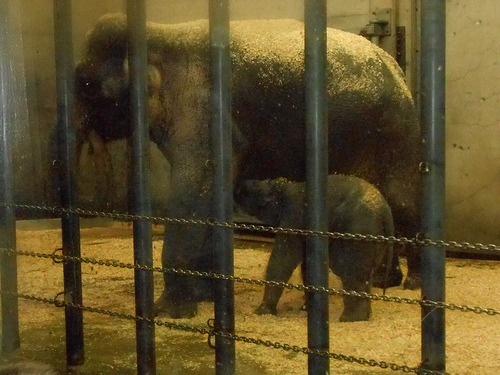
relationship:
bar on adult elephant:
[50, 0, 83, 370] [46, 12, 434, 318]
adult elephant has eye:
[46, 12, 434, 318] [66, 70, 103, 110]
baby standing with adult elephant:
[231, 172, 396, 323] [73, 12, 433, 307]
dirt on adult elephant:
[146, 16, 411, 97] [46, 12, 434, 318]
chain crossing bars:
[0, 199, 499, 259] [49, 4, 449, 371]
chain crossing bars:
[0, 246, 497, 313] [49, 4, 449, 371]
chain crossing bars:
[3, 285, 447, 373] [49, 4, 449, 371]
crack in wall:
[448, 34, 488, 81] [10, 3, 496, 257]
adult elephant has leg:
[46, 12, 434, 318] [141, 141, 223, 289]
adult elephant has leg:
[46, 12, 434, 318] [146, 201, 231, 306]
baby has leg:
[231, 172, 396, 323] [252, 228, 307, 318]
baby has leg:
[231, 172, 396, 323] [332, 271, 387, 326]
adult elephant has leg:
[46, 12, 434, 318] [383, 161, 445, 287]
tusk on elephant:
[80, 124, 115, 180] [40, 18, 491, 273]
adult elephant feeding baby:
[46, 12, 434, 318] [231, 172, 396, 323]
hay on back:
[363, 184, 381, 209] [328, 168, 397, 223]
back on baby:
[328, 168, 397, 223] [231, 172, 402, 323]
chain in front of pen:
[275, 274, 497, 314] [2, 4, 498, 372]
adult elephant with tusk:
[46, 12, 434, 318] [83, 122, 115, 176]